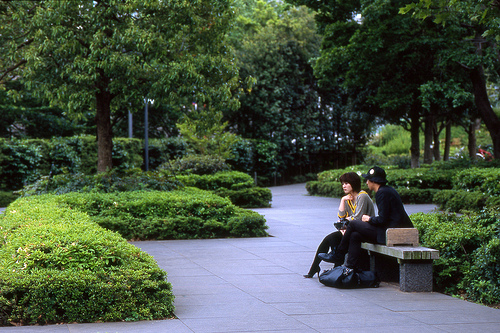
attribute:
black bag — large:
[307, 256, 373, 286]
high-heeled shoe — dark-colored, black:
[302, 265, 325, 281]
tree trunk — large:
[93, 100, 119, 176]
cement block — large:
[297, 308, 393, 325]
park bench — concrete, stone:
[376, 239, 442, 288]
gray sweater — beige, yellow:
[337, 190, 375, 219]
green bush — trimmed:
[162, 149, 280, 213]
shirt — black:
[373, 183, 411, 232]